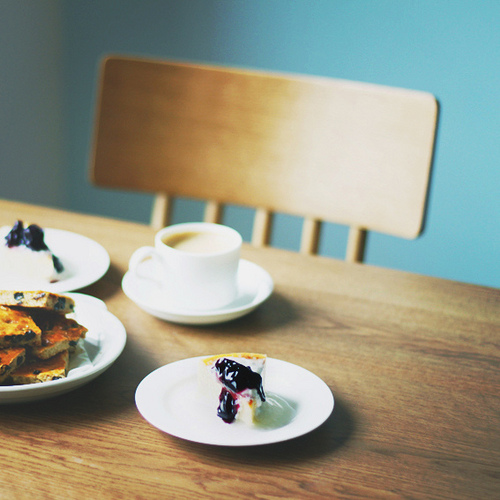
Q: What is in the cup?
A: Coffee.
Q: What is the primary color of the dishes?
A: White.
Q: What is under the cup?
A: Saucer.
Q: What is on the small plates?
A: Dessert.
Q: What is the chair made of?
A: Wood.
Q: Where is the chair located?
A: Next to table.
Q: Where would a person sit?
A: Chair.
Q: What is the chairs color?
A: Tan.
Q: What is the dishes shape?
A: Circular.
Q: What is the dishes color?
A: White.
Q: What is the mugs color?
A: White.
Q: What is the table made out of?
A: Wood.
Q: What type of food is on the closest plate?
A: Dessert.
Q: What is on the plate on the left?
A: Baked goods.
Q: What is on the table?
A: Baked foods and coffee.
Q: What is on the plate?
A: Pie.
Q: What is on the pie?
A: Blueberries.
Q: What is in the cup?
A: Coffee.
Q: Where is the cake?
A: Table.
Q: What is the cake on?
A: Plate.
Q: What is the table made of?
A: Wood.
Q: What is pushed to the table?
A: Chair.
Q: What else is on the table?
A: Cookies.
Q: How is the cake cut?
A: Slices.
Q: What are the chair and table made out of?
A: Wood.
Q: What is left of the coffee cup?
A: Plate of food.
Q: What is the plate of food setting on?
A: Wood table.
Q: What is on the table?
A: Tea and cake.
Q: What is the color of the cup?
A: White.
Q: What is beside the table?
A: Chair.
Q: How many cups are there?
A: 1.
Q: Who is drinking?
A: No one.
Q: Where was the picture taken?
A: At a dining table.